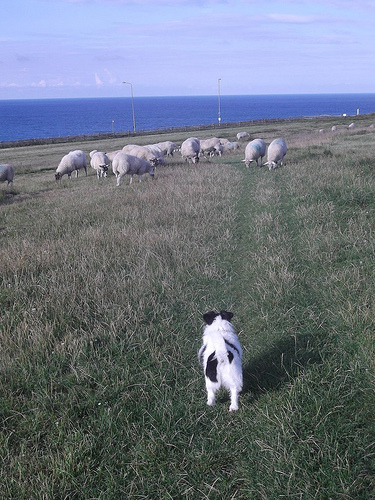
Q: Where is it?
A: This is at the field.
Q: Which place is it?
A: It is a field.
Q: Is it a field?
A: Yes, it is a field.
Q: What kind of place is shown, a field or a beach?
A: It is a field.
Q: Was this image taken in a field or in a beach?
A: It was taken at a field.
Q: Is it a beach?
A: No, it is a field.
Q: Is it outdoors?
A: Yes, it is outdoors.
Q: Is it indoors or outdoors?
A: It is outdoors.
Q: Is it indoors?
A: No, it is outdoors.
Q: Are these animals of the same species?
A: No, they are sheep and dogs.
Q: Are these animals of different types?
A: Yes, they are sheep and dogs.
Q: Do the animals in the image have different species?
A: Yes, they are sheep and dogs.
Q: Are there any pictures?
A: No, there are no pictures.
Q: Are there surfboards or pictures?
A: No, there are no pictures or surfboards.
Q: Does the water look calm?
A: Yes, the water is calm.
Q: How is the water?
A: The water is calm.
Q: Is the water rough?
A: No, the water is calm.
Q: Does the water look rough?
A: No, the water is calm.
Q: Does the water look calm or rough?
A: The water is calm.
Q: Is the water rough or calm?
A: The water is calm.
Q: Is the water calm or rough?
A: The water is calm.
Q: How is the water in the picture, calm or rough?
A: The water is calm.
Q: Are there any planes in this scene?
A: No, there are no planes.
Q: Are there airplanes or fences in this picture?
A: No, there are no airplanes or fences.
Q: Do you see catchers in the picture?
A: No, there are no catchers.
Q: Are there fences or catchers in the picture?
A: No, there are no catchers or fences.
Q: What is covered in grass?
A: The field is covered in grass.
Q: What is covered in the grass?
A: The field is covered in grass.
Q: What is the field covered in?
A: The field is covered in grass.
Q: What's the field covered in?
A: The field is covered in grass.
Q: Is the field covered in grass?
A: Yes, the field is covered in grass.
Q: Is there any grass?
A: Yes, there is grass.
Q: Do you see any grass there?
A: Yes, there is grass.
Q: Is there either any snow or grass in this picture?
A: Yes, there is grass.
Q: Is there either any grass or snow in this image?
A: Yes, there is grass.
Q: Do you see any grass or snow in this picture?
A: Yes, there is grass.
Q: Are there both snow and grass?
A: No, there is grass but no snow.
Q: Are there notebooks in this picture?
A: No, there are no notebooks.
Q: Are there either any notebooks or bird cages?
A: No, there are no notebooks or bird cages.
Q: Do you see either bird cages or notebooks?
A: No, there are no notebooks or bird cages.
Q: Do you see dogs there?
A: Yes, there is a dog.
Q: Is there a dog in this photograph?
A: Yes, there is a dog.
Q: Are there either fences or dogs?
A: Yes, there is a dog.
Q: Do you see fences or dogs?
A: Yes, there is a dog.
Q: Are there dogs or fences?
A: Yes, there is a dog.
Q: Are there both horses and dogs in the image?
A: No, there is a dog but no horses.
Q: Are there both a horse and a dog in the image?
A: No, there is a dog but no horses.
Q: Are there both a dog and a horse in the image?
A: No, there is a dog but no horses.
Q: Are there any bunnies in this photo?
A: No, there are no bunnies.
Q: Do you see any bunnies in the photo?
A: No, there are no bunnies.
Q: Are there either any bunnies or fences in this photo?
A: No, there are no bunnies or fences.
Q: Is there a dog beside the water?
A: Yes, there is a dog beside the water.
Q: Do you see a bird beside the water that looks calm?
A: No, there is a dog beside the water.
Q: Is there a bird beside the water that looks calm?
A: No, there is a dog beside the water.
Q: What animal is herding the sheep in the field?
A: The dog is herding the sheep.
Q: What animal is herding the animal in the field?
A: The dog is herding the sheep.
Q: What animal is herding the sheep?
A: The dog is herding the sheep.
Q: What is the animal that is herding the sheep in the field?
A: The animal is a dog.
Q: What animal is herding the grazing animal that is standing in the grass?
A: The animal is a dog.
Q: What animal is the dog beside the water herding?
A: The dog is herding the sheep.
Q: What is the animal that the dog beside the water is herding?
A: The animal is a sheep.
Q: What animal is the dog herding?
A: The dog is herding the sheep.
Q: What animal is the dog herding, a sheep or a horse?
A: The dog is herding a sheep.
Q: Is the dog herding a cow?
A: No, the dog is herding the sheep.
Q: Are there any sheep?
A: Yes, there is a sheep.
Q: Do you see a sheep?
A: Yes, there is a sheep.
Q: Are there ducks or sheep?
A: Yes, there is a sheep.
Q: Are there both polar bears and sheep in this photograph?
A: No, there is a sheep but no polar bears.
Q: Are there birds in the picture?
A: No, there are no birds.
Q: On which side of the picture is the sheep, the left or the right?
A: The sheep is on the right of the image.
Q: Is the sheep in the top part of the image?
A: Yes, the sheep is in the top of the image.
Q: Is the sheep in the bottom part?
A: No, the sheep is in the top of the image.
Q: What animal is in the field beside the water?
A: The animal is a sheep.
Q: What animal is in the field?
A: The animal is a sheep.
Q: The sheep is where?
A: The sheep is in the field.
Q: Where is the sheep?
A: The sheep is in the field.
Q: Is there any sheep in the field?
A: Yes, there is a sheep in the field.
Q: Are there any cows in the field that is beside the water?
A: No, there is a sheep in the field.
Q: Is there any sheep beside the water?
A: Yes, there is a sheep beside the water.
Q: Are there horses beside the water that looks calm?
A: No, there is a sheep beside the water.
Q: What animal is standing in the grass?
A: The sheep is standing in the grass.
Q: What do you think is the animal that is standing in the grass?
A: The animal is a sheep.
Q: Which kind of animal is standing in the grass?
A: The animal is a sheep.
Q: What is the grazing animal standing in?
A: The sheep is standing in the grass.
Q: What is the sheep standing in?
A: The sheep is standing in the grass.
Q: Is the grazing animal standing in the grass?
A: Yes, the sheep is standing in the grass.